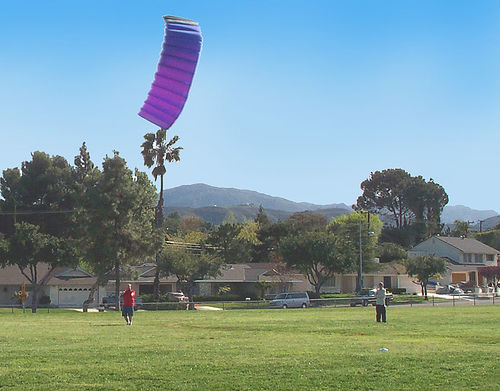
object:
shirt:
[117, 288, 139, 312]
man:
[113, 281, 138, 325]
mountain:
[162, 178, 355, 224]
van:
[267, 290, 311, 310]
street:
[193, 298, 499, 311]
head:
[126, 281, 133, 292]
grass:
[0, 325, 498, 391]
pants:
[373, 304, 389, 323]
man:
[369, 279, 393, 325]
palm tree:
[139, 128, 183, 226]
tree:
[350, 166, 450, 238]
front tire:
[279, 303, 289, 310]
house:
[404, 234, 500, 287]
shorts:
[121, 305, 133, 317]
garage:
[52, 285, 101, 308]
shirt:
[373, 288, 388, 307]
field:
[1, 325, 500, 391]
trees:
[265, 225, 361, 299]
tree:
[0, 149, 89, 314]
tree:
[65, 141, 166, 311]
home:
[1, 257, 100, 311]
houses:
[307, 244, 426, 294]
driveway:
[61, 303, 107, 316]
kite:
[135, 14, 203, 134]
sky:
[202, 0, 499, 167]